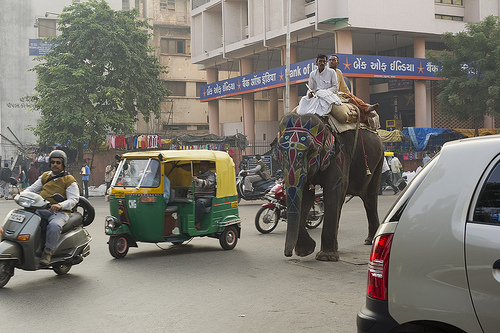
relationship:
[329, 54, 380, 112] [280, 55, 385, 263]
man rides elephant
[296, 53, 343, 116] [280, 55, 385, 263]
man rides elephant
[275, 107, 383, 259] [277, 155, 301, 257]
elephant has trunk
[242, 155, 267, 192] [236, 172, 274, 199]
man rides scooter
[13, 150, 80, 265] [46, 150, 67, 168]
man wears helmet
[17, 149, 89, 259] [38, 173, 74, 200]
man wears vest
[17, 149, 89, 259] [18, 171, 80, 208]
man wears shirt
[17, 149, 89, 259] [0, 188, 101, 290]
man on scooter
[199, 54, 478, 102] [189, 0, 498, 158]
sign on building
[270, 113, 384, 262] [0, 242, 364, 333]
elephant on road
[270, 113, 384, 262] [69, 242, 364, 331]
elephant walking on road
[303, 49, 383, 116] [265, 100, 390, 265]
people on elephant